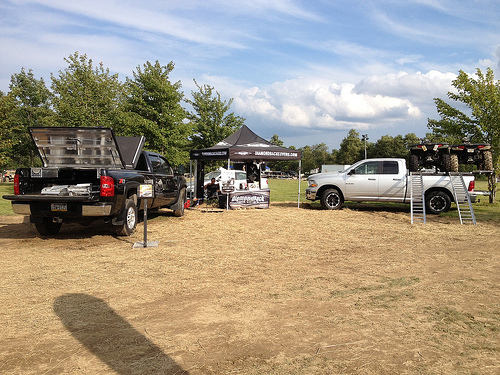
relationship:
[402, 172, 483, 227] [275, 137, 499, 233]
ladders on truck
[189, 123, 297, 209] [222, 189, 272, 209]
tent on table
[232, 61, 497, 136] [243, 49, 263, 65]
clouds on sky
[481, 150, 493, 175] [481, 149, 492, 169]
wheels covered in dirt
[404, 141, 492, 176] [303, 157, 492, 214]
four wheeler on top of truck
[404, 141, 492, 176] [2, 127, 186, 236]
four wheeler on top of truck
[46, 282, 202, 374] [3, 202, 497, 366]
shadow on ground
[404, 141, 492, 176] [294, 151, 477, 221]
four wheeler on truck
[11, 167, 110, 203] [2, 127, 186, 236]
bed of truck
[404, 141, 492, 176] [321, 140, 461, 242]
four wheeler in bed of truck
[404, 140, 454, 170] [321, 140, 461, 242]
four wheeler in bed of truck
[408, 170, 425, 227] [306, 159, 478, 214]
ramp for truck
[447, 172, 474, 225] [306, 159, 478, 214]
ramp for truck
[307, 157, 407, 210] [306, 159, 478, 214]
cab of truck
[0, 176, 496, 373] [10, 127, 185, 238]
ground behind pickup truck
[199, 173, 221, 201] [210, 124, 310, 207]
man under tent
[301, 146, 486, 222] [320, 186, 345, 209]
truck has wheel